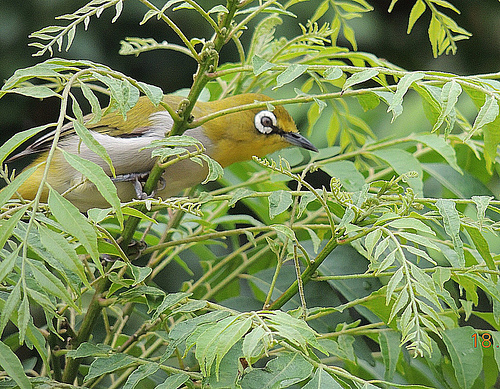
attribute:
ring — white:
[254, 110, 277, 136]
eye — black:
[261, 118, 273, 128]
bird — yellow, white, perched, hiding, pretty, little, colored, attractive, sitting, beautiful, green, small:
[0, 90, 322, 214]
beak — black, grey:
[286, 132, 320, 153]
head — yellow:
[206, 90, 321, 170]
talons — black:
[109, 171, 168, 202]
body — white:
[46, 88, 223, 216]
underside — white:
[58, 108, 220, 214]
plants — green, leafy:
[3, 0, 498, 388]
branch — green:
[50, 0, 250, 388]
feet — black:
[101, 168, 166, 266]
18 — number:
[469, 330, 493, 351]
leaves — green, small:
[361, 207, 448, 365]